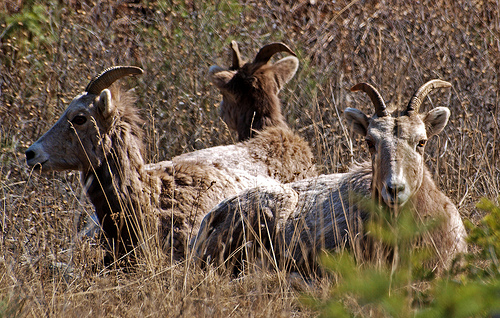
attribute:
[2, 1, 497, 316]
brown grass — dead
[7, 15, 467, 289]
grass — dry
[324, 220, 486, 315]
vegetation — green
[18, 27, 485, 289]
rams — brown, white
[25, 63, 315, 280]
animal — laying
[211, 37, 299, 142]
animal — laying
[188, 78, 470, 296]
animal — three, laying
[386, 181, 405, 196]
nose — black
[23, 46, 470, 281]
animals — herd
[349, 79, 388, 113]
horn — curved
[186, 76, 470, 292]
goat — brown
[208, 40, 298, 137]
goat — brown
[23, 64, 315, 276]
goat — brown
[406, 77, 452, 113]
horn — curved